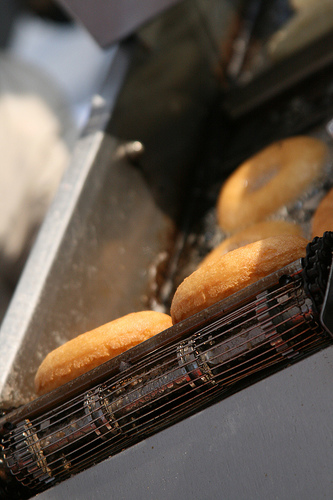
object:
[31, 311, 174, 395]
food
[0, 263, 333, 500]
gear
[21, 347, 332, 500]
wall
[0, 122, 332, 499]
fryer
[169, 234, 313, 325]
donut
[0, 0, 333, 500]
machine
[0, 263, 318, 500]
wire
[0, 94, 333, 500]
light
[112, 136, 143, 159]
stud